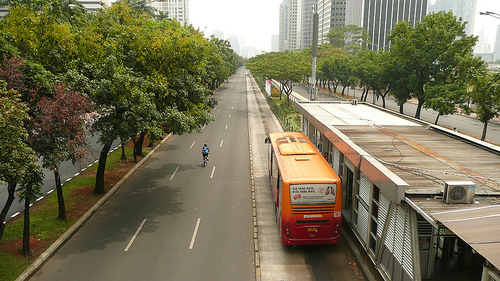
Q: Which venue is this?
A: This is a highway.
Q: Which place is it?
A: It is a highway.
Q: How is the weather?
A: It is cloudy.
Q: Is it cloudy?
A: Yes, it is cloudy.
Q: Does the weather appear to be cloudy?
A: Yes, it is cloudy.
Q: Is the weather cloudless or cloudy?
A: It is cloudy.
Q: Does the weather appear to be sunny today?
A: No, it is cloudy.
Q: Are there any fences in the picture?
A: No, there are no fences.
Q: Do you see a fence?
A: No, there are no fences.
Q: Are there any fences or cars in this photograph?
A: No, there are no fences or cars.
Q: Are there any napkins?
A: No, there are no napkins.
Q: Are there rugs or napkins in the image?
A: No, there are no napkins or rugs.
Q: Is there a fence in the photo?
A: No, there are no fences.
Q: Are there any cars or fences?
A: No, there are no fences or cars.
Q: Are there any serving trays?
A: No, there are no serving trays.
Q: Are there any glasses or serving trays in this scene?
A: No, there are no serving trays or glasses.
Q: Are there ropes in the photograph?
A: No, there are no ropes.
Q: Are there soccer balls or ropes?
A: No, there are no ropes or soccer balls.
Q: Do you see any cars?
A: No, there are no cars.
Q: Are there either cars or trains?
A: No, there are no cars or trains.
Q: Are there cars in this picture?
A: No, there are no cars.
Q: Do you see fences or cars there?
A: No, there are no cars or fences.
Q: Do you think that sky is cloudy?
A: Yes, the sky is cloudy.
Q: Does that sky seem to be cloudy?
A: Yes, the sky is cloudy.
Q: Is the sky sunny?
A: No, the sky is cloudy.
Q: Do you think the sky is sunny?
A: No, the sky is cloudy.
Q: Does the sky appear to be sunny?
A: No, the sky is cloudy.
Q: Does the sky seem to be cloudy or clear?
A: The sky is cloudy.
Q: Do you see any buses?
A: Yes, there is a bus.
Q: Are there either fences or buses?
A: Yes, there is a bus.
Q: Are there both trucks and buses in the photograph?
A: No, there is a bus but no trucks.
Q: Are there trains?
A: No, there are no trains.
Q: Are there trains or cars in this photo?
A: No, there are no trains or cars.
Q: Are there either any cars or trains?
A: No, there are no trains or cars.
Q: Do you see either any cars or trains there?
A: No, there are no trains or cars.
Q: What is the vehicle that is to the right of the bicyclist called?
A: The vehicle is a bus.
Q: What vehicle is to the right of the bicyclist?
A: The vehicle is a bus.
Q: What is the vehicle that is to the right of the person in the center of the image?
A: The vehicle is a bus.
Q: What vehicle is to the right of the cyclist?
A: The vehicle is a bus.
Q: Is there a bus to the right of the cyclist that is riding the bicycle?
A: Yes, there is a bus to the right of the bicyclist.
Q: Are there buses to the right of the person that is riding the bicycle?
A: Yes, there is a bus to the right of the bicyclist.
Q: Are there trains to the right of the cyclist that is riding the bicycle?
A: No, there is a bus to the right of the cyclist.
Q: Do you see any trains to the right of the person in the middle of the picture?
A: No, there is a bus to the right of the cyclist.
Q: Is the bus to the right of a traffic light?
A: No, the bus is to the right of a cyclist.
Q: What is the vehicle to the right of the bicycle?
A: The vehicle is a bus.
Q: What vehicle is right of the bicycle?
A: The vehicle is a bus.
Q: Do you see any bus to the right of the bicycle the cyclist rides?
A: Yes, there is a bus to the right of the bicycle.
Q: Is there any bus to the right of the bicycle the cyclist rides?
A: Yes, there is a bus to the right of the bicycle.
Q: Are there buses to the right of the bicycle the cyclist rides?
A: Yes, there is a bus to the right of the bicycle.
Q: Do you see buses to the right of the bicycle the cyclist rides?
A: Yes, there is a bus to the right of the bicycle.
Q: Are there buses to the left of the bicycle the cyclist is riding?
A: No, the bus is to the right of the bicycle.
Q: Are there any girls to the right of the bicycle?
A: No, there is a bus to the right of the bicycle.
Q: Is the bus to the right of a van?
A: No, the bus is to the right of a bicycle.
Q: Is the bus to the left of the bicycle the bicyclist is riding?
A: No, the bus is to the right of the bicycle.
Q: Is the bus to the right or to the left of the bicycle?
A: The bus is to the right of the bicycle.